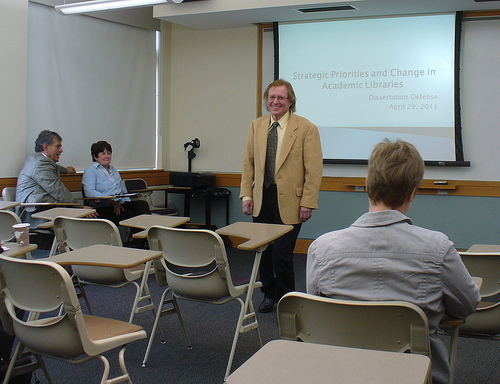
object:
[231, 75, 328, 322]
man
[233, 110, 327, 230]
coat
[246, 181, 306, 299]
black pants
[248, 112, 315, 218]
jacket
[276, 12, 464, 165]
screen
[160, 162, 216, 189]
projector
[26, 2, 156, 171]
shade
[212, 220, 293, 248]
desk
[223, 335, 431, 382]
desk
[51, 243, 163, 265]
desk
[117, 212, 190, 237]
desk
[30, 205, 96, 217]
desk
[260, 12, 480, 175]
screen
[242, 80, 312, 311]
person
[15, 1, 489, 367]
class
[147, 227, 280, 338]
chair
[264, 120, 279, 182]
man's tie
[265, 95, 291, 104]
eyeglasses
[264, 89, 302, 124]
face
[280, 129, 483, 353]
person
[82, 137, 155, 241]
person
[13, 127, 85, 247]
person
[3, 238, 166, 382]
desk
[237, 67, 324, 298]
adult male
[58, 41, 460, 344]
room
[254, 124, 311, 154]
shirt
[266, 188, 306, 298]
pants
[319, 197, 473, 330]
jacket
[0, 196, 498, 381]
desks